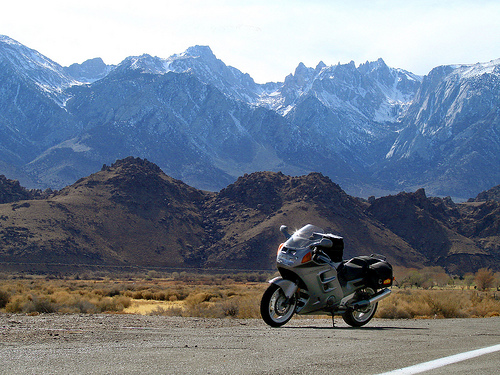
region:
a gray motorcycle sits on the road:
[234, 203, 402, 372]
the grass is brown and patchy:
[11, 255, 498, 322]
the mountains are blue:
[1, 27, 499, 189]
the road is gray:
[5, 307, 497, 373]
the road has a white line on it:
[239, 306, 499, 373]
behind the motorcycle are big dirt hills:
[1, 145, 498, 290]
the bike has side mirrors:
[253, 211, 398, 333]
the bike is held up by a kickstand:
[247, 211, 397, 339]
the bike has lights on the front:
[252, 216, 350, 283]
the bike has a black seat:
[286, 216, 396, 292]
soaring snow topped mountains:
[0, 35, 496, 162]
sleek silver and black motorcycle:
[257, 222, 391, 332]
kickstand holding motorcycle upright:
[327, 313, 337, 328]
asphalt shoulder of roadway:
[15, 320, 497, 371]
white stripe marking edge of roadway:
[382, 343, 499, 371]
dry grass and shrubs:
[0, 273, 499, 320]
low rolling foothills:
[0, 174, 499, 281]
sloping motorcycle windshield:
[293, 223, 319, 238]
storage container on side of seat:
[369, 257, 394, 289]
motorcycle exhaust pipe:
[349, 287, 402, 304]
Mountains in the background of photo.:
[3, 35, 498, 177]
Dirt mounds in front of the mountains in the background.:
[6, 171, 499, 280]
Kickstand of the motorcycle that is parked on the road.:
[328, 308, 341, 330]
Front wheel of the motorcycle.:
[261, 276, 295, 324]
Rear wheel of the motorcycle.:
[343, 291, 383, 327]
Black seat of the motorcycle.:
[340, 253, 393, 288]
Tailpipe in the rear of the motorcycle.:
[343, 290, 399, 310]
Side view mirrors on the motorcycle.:
[276, 217, 336, 254]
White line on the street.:
[370, 321, 495, 373]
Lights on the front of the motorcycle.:
[272, 238, 319, 265]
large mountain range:
[1, 33, 498, 203]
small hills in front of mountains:
[1, 155, 498, 277]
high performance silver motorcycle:
[258, 223, 395, 328]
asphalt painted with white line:
[0, 313, 498, 374]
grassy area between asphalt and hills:
[0, 266, 498, 318]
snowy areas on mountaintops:
[0, 34, 499, 124]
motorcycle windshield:
[279, 222, 323, 264]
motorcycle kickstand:
[328, 310, 338, 327]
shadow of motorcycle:
[279, 321, 433, 333]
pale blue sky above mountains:
[0, 0, 499, 82]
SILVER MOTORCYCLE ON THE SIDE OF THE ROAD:
[255, 210, 400, 352]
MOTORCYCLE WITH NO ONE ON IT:
[261, 205, 396, 352]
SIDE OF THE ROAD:
[17, 307, 498, 364]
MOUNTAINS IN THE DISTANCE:
[30, 59, 485, 202]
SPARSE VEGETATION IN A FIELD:
[12, 257, 497, 327]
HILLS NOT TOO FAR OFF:
[13, 164, 498, 299]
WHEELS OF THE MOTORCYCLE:
[259, 272, 393, 339]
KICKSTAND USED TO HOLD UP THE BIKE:
[318, 284, 348, 344]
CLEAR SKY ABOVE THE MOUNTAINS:
[11, 14, 488, 161]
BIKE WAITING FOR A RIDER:
[260, 207, 400, 350]